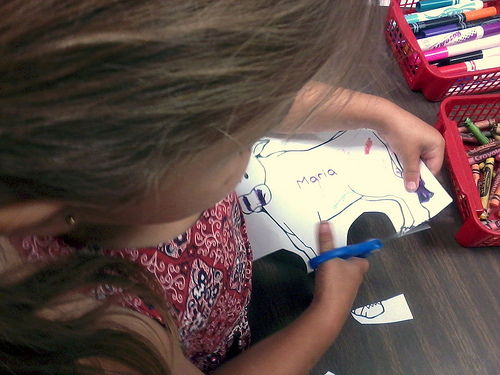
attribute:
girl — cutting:
[3, 0, 445, 374]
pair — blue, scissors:
[308, 222, 436, 266]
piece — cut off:
[351, 294, 415, 327]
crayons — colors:
[457, 115, 497, 234]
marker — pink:
[424, 34, 500, 61]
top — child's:
[0, 1, 380, 62]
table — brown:
[249, 2, 499, 373]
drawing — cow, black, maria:
[232, 124, 429, 268]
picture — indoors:
[4, 2, 499, 374]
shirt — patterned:
[0, 190, 254, 371]